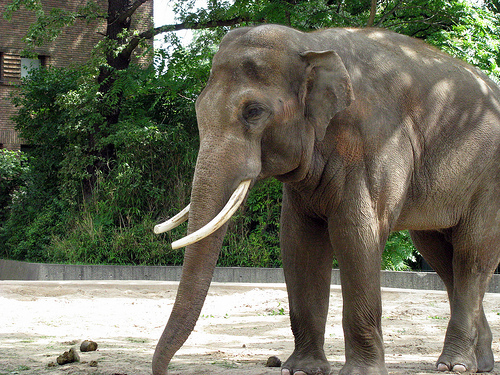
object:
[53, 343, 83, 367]
elephant excrement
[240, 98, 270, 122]
eye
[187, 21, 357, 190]
head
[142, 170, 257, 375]
trunk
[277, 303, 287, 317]
leaves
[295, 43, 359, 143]
ear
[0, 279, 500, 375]
dirt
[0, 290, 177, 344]
sun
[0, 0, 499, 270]
tree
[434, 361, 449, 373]
toe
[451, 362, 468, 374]
toe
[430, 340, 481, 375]
foot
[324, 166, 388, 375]
leg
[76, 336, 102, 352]
elephant poop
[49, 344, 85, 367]
dung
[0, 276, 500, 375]
ground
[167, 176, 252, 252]
elephant tusks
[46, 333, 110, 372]
poop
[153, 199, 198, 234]
tusks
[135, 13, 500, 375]
animal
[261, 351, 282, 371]
excrement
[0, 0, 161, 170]
building